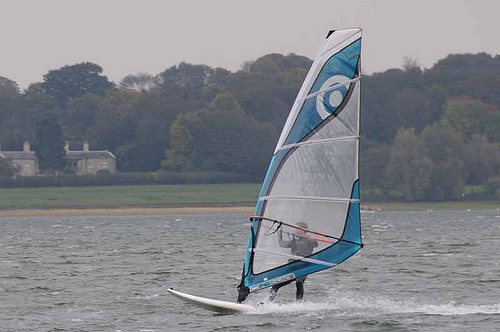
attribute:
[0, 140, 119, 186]
house — white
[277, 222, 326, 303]
man — windsurfing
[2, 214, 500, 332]
water — choppy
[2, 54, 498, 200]
trees — large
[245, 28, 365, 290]
sail — transparent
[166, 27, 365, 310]
equipment — white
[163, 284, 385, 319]
surfboard — white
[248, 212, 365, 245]
handle — black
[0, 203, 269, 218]
beach — sandy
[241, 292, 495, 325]
wake — small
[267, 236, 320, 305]
suit — black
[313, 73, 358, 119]
circle — white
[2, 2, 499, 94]
skies — grey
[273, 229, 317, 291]
wetsuit — black